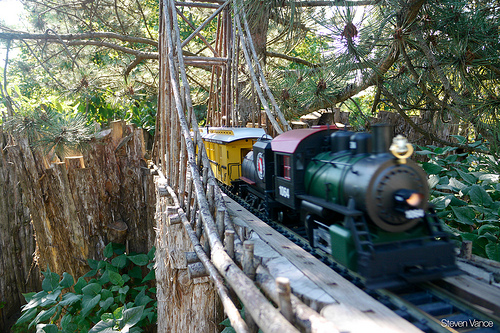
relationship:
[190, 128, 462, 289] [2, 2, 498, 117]
black train going through trees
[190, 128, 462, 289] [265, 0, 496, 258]
black train going through tree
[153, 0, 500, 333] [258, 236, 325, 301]
bridge made of wood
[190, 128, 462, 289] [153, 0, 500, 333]
black train moving on bridge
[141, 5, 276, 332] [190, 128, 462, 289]
bridge strut support near black train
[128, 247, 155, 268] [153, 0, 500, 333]
leaf below bridge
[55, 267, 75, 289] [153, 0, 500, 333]
leaf below bridge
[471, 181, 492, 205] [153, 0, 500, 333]
leaf below bridge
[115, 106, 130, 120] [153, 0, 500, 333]
leaf below bridge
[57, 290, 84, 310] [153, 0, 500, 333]
leaf below bridge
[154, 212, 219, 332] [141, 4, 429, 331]
support of bridge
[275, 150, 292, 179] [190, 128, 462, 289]
window of black train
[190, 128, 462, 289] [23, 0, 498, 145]
black train going through trees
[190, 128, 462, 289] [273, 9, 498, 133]
black train going through trees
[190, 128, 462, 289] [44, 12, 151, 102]
black train going through trees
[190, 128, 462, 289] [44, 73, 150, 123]
black train going through trees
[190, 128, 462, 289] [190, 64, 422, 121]
black train going through trees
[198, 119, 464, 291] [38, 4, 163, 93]
black train going through trees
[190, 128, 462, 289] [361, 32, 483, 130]
black train going through trees